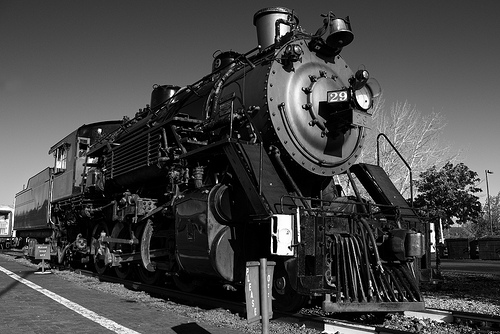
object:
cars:
[0, 205, 15, 255]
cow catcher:
[301, 216, 471, 319]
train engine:
[15, 3, 425, 311]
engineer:
[53, 24, 470, 322]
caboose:
[14, 165, 53, 232]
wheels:
[4, 227, 170, 280]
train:
[12, 7, 430, 323]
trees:
[364, 99, 484, 267]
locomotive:
[85, 6, 440, 331]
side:
[16, 82, 288, 278]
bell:
[325, 15, 354, 50]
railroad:
[1, 223, 498, 332]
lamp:
[483, 169, 497, 258]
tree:
[405, 158, 483, 276]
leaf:
[462, 167, 473, 176]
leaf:
[449, 182, 456, 203]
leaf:
[421, 168, 432, 177]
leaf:
[420, 198, 432, 211]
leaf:
[470, 202, 478, 221]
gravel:
[319, 314, 381, 331]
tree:
[367, 86, 447, 188]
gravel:
[431, 309, 483, 322]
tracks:
[289, 285, 474, 332]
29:
[325, 90, 350, 104]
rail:
[317, 307, 496, 331]